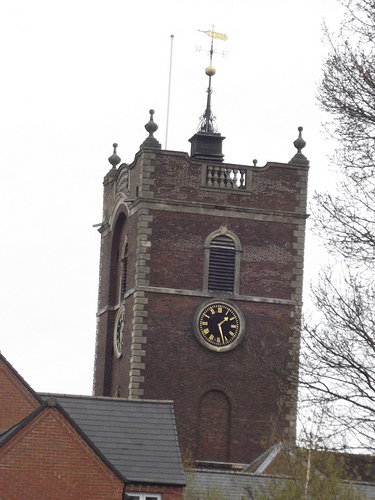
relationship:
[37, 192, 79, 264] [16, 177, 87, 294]
sky has clouds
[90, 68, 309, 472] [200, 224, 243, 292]
tower has window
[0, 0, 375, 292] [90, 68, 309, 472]
sky next to tower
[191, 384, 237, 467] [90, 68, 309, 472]
arch on side of tower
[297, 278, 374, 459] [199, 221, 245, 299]
tree in front of window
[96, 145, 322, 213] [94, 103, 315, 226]
top of roof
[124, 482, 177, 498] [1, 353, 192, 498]
top window on building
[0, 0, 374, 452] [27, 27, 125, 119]
cloud in sky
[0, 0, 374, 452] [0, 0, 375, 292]
cloud in sky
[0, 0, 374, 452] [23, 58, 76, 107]
cloud in sky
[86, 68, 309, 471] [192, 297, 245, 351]
tower showing time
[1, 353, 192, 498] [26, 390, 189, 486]
building with roof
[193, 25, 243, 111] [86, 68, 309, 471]
vane on top of tower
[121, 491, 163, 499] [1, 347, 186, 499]
window on house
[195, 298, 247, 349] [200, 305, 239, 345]
black clock with roman numberals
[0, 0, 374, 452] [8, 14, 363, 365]
cloud in sky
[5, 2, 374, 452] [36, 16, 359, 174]
cloud in sky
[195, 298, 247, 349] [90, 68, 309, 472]
black clock on tower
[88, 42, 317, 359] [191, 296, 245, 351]
clock tower with clock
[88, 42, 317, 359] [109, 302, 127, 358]
clock tower with clock